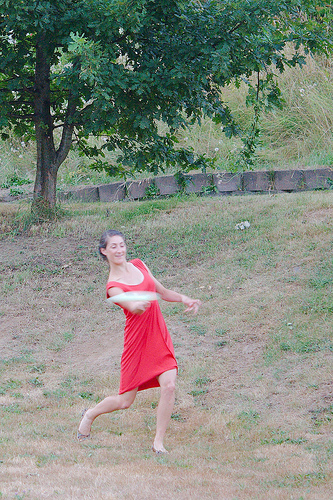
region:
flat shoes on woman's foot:
[64, 431, 119, 452]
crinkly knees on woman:
[156, 377, 176, 396]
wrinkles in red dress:
[119, 347, 154, 361]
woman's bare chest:
[98, 266, 146, 287]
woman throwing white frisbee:
[99, 280, 185, 316]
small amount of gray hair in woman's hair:
[97, 227, 117, 249]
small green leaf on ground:
[275, 314, 302, 340]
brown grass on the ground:
[54, 454, 126, 484]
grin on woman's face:
[91, 248, 147, 266]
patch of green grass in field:
[17, 254, 65, 296]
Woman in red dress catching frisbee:
[74, 229, 209, 462]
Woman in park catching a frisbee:
[69, 216, 211, 458]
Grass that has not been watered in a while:
[205, 333, 330, 491]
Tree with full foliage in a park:
[8, 4, 206, 229]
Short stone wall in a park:
[73, 161, 327, 214]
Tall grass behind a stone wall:
[231, 94, 330, 210]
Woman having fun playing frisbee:
[71, 217, 219, 463]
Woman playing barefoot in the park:
[59, 225, 210, 464]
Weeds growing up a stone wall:
[136, 169, 226, 207]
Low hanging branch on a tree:
[205, 51, 314, 202]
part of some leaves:
[138, 63, 180, 123]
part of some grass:
[226, 384, 261, 432]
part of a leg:
[151, 408, 172, 450]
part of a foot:
[75, 420, 96, 442]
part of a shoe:
[74, 431, 86, 445]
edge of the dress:
[132, 374, 154, 396]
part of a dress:
[133, 358, 153, 374]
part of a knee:
[152, 367, 194, 415]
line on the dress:
[158, 330, 185, 364]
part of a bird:
[123, 287, 156, 306]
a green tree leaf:
[87, 79, 100, 90]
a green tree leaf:
[140, 74, 148, 83]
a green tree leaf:
[142, 122, 147, 128]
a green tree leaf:
[155, 154, 160, 161]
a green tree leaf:
[191, 114, 201, 124]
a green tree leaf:
[104, 160, 110, 169]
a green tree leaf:
[87, 117, 94, 126]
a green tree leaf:
[203, 156, 206, 162]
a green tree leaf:
[71, 84, 76, 92]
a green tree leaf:
[80, 66, 86, 77]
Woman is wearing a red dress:
[65, 216, 204, 399]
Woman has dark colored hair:
[87, 225, 136, 271]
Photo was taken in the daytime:
[18, 11, 319, 480]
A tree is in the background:
[4, 5, 318, 213]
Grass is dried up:
[53, 456, 240, 492]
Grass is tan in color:
[74, 466, 241, 495]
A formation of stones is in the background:
[86, 167, 331, 211]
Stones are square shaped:
[128, 156, 332, 204]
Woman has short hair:
[70, 227, 142, 275]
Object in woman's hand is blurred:
[97, 280, 167, 325]